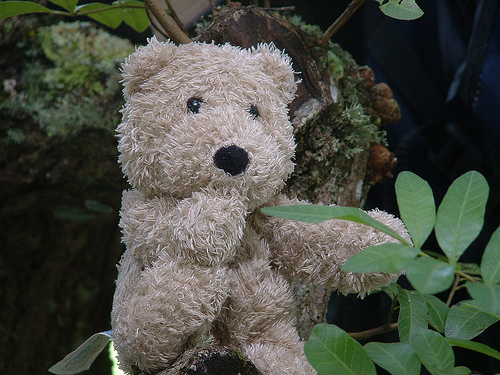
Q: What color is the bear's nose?
A: Black.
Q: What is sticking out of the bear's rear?
A: A tag.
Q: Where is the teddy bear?
A: Sitting in a tree.